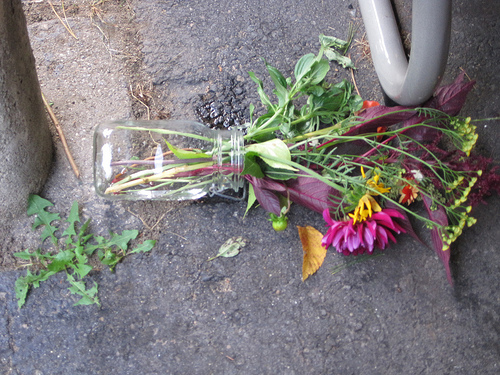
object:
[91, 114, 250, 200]
jar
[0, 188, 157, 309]
dandelion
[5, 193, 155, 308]
crack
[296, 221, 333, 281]
leaf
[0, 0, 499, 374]
pavement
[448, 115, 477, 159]
flowers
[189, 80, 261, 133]
water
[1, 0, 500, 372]
ground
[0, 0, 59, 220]
post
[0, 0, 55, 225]
base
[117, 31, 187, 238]
grass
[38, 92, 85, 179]
twig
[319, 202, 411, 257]
flower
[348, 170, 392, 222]
black eyed susan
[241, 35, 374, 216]
leaves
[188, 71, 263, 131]
spot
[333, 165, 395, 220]
flowers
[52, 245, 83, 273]
stem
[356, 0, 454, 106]
bar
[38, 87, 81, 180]
stick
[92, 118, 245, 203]
vase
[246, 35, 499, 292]
bunch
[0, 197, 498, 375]
side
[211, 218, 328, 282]
stuff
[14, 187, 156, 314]
weed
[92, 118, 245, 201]
glass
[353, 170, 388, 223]
flower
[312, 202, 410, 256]
petals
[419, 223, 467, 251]
flowers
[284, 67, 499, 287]
bouquet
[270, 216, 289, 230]
berry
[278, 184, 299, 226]
stem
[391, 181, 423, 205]
flower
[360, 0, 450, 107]
piece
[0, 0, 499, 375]
surface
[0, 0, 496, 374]
asphalt